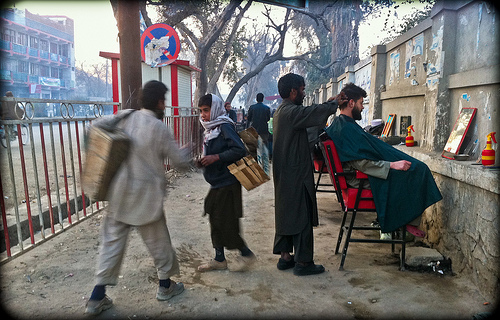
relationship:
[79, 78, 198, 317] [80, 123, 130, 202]
man carrying basket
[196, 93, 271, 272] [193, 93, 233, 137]
person with scarf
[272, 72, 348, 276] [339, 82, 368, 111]
barber giving hair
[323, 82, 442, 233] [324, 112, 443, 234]
man wearing cape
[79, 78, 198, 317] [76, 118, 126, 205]
man carrying basket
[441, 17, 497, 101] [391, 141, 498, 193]
stone wall with ledge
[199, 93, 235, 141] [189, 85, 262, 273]
headwrap of woman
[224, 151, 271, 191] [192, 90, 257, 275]
purse of woman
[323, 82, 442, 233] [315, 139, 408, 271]
man in barber's chair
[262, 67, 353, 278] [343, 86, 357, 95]
barber in hair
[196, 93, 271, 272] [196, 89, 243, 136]
person in scarf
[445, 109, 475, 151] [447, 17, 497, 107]
mirror against stone wall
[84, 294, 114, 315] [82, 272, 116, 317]
foot on foot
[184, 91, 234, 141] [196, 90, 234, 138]
person wearing headwrap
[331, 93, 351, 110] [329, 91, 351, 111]
clippers are on hand